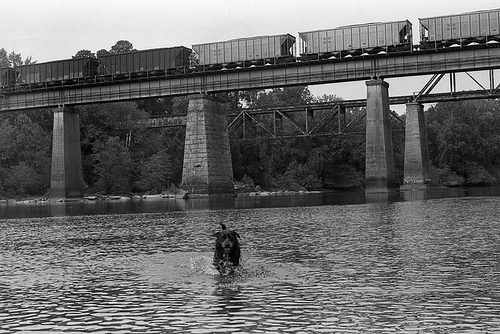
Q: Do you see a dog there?
A: Yes, there is a dog.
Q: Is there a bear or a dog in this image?
A: Yes, there is a dog.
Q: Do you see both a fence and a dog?
A: No, there is a dog but no fences.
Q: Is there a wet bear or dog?
A: Yes, there is a wet dog.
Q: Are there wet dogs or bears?
A: Yes, there is a wet dog.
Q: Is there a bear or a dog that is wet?
A: Yes, the dog is wet.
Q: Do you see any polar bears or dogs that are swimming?
A: Yes, the dog is swimming.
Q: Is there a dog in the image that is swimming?
A: Yes, there is a dog that is swimming.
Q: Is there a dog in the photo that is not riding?
A: Yes, there is a dog that is swimming.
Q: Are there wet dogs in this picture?
A: Yes, there is a wet dog.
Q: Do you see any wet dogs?
A: Yes, there is a wet dog.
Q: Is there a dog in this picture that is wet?
A: Yes, there is a dog that is wet.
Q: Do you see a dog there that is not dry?
A: Yes, there is a wet dog.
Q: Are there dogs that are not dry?
A: Yes, there is a wet dog.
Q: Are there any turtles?
A: No, there are no turtles.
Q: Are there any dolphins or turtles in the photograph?
A: No, there are no turtles or dolphins.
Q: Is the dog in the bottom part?
A: Yes, the dog is in the bottom of the image.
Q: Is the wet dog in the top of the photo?
A: No, the dog is in the bottom of the image.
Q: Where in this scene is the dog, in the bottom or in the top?
A: The dog is in the bottom of the image.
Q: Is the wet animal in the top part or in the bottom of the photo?
A: The dog is in the bottom of the image.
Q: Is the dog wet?
A: Yes, the dog is wet.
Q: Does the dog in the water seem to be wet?
A: Yes, the dog is wet.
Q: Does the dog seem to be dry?
A: No, the dog is wet.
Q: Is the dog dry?
A: No, the dog is wet.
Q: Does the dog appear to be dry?
A: No, the dog is wet.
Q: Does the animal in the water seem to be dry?
A: No, the dog is wet.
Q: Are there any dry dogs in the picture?
A: No, there is a dog but it is wet.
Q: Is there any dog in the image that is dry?
A: No, there is a dog but it is wet.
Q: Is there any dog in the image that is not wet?
A: No, there is a dog but it is wet.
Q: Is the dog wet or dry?
A: The dog is wet.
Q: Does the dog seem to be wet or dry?
A: The dog is wet.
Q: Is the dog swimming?
A: Yes, the dog is swimming.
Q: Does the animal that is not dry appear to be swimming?
A: Yes, the dog is swimming.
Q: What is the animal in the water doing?
A: The dog is swimming.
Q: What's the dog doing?
A: The dog is swimming.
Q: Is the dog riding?
A: No, the dog is swimming.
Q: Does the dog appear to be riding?
A: No, the dog is swimming.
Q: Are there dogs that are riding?
A: No, there is a dog but it is swimming.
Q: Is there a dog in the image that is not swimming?
A: No, there is a dog but it is swimming.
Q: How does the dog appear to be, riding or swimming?
A: The dog is swimming.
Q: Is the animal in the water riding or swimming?
A: The dog is swimming.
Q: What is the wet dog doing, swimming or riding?
A: The dog is swimming.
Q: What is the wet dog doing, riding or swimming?
A: The dog is swimming.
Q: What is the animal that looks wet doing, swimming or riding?
A: The dog is swimming.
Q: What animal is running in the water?
A: The dog is running in the water.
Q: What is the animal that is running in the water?
A: The animal is a dog.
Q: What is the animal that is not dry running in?
A: The dog is running in the water.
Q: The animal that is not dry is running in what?
A: The dog is running in the water.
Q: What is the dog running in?
A: The dog is running in the water.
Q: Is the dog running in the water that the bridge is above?
A: Yes, the dog is running in the water.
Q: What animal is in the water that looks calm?
A: The dog is in the water.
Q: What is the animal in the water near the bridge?
A: The animal is a dog.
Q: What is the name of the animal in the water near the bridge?
A: The animal is a dog.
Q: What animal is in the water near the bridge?
A: The animal is a dog.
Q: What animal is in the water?
A: The animal is a dog.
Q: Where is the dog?
A: The dog is in the water.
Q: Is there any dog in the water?
A: Yes, there is a dog in the water.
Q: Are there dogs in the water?
A: Yes, there is a dog in the water.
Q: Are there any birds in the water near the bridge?
A: No, there is a dog in the water.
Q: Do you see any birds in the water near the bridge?
A: No, there is a dog in the water.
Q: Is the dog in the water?
A: Yes, the dog is in the water.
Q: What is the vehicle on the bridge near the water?
A: The vehicle is a car.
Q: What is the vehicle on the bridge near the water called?
A: The vehicle is a car.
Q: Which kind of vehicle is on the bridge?
A: The vehicle is a car.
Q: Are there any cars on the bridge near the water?
A: Yes, there is a car on the bridge.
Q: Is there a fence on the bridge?
A: No, there is a car on the bridge.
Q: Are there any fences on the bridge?
A: No, there is a car on the bridge.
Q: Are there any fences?
A: No, there are no fences.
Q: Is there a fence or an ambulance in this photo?
A: No, there are no fences or ambulances.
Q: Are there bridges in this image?
A: Yes, there is a bridge.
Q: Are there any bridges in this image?
A: Yes, there is a bridge.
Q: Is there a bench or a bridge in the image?
A: Yes, there is a bridge.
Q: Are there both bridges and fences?
A: No, there is a bridge but no fences.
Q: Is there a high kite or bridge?
A: Yes, there is a high bridge.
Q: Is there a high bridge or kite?
A: Yes, there is a high bridge.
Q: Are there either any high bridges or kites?
A: Yes, there is a high bridge.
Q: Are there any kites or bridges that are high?
A: Yes, the bridge is high.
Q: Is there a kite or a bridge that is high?
A: Yes, the bridge is high.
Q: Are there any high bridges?
A: Yes, there is a high bridge.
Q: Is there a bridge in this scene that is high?
A: Yes, there is a bridge that is high.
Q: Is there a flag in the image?
A: No, there are no flags.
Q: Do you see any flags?
A: No, there are no flags.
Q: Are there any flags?
A: No, there are no flags.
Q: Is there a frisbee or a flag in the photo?
A: No, there are no flags or frisbees.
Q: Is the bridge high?
A: Yes, the bridge is high.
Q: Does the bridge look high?
A: Yes, the bridge is high.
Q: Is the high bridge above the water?
A: Yes, the bridge is above the water.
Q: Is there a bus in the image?
A: No, there are no buses.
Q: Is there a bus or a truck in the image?
A: No, there are no buses or trucks.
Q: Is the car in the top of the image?
A: Yes, the car is in the top of the image.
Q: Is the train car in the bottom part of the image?
A: No, the car is in the top of the image.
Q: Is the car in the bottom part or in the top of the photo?
A: The car is in the top of the image.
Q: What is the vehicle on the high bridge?
A: The vehicle is a car.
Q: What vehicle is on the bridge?
A: The vehicle is a car.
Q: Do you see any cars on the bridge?
A: Yes, there is a car on the bridge.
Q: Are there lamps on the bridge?
A: No, there is a car on the bridge.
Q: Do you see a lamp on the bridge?
A: No, there is a car on the bridge.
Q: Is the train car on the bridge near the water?
A: Yes, the car is on the bridge.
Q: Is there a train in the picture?
A: Yes, there is a train.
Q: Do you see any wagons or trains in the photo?
A: Yes, there is a train.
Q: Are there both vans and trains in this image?
A: No, there is a train but no vans.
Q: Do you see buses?
A: No, there are no buses.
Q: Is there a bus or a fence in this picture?
A: No, there are no buses or fences.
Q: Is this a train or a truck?
A: This is a train.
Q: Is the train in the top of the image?
A: Yes, the train is in the top of the image.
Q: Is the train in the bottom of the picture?
A: No, the train is in the top of the image.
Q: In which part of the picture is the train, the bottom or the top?
A: The train is in the top of the image.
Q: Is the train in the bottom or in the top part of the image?
A: The train is in the top of the image.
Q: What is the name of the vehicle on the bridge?
A: The vehicle is a train.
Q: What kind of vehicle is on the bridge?
A: The vehicle is a train.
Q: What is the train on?
A: The train is on the bridge.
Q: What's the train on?
A: The train is on the bridge.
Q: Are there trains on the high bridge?
A: Yes, there is a train on the bridge.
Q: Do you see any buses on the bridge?
A: No, there is a train on the bridge.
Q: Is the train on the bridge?
A: Yes, the train is on the bridge.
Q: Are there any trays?
A: No, there are no trays.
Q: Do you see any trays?
A: No, there are no trays.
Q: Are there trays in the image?
A: No, there are no trays.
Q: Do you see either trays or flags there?
A: No, there are no trays or flags.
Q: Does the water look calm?
A: Yes, the water is calm.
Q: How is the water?
A: The water is calm.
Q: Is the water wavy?
A: No, the water is calm.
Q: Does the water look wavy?
A: No, the water is calm.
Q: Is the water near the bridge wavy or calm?
A: The water is calm.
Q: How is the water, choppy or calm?
A: The water is calm.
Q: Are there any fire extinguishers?
A: No, there are no fire extinguishers.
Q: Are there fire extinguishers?
A: No, there are no fire extinguishers.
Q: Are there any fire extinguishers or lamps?
A: No, there are no fire extinguishers or lamps.